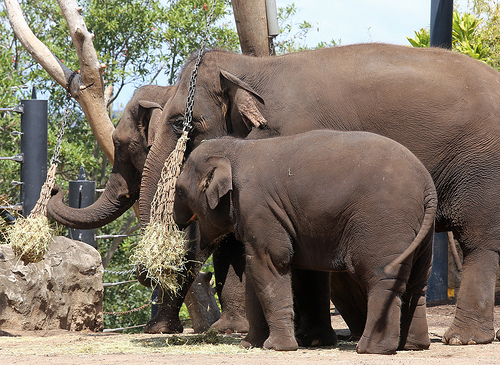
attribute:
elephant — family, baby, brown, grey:
[177, 123, 432, 350]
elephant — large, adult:
[142, 39, 499, 346]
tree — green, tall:
[0, 3, 118, 164]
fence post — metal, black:
[18, 104, 50, 220]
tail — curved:
[385, 171, 441, 283]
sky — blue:
[9, 2, 500, 103]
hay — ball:
[127, 216, 197, 291]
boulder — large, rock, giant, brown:
[0, 234, 108, 332]